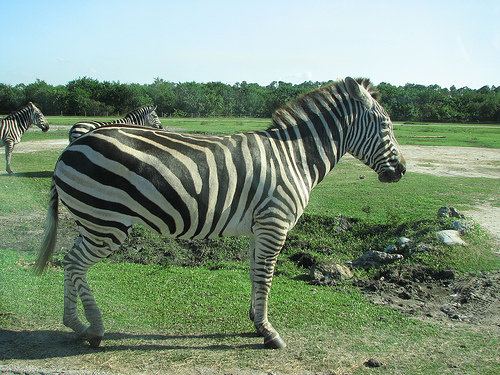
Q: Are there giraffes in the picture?
A: No, there are no giraffes.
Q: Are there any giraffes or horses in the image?
A: No, there are no giraffes or horses.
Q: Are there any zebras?
A: Yes, there is a zebra.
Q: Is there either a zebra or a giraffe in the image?
A: Yes, there is a zebra.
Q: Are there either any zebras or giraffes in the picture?
A: Yes, there is a zebra.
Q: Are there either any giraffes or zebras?
A: Yes, there is a zebra.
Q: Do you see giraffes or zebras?
A: Yes, there is a zebra.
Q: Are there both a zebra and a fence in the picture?
A: No, there is a zebra but no fences.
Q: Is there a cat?
A: No, there are no cats.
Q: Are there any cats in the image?
A: No, there are no cats.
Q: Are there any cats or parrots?
A: No, there are no cats or parrots.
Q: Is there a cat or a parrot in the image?
A: No, there are no cats or parrots.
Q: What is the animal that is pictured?
A: The animal is a zebra.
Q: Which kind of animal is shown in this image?
A: The animal is a zebra.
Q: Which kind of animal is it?
A: The animal is a zebra.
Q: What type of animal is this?
A: That is a zebra.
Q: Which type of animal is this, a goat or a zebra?
A: That is a zebra.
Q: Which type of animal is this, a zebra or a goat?
A: That is a zebra.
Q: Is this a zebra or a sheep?
A: This is a zebra.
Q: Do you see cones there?
A: No, there are no cones.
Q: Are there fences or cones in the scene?
A: No, there are no cones or fences.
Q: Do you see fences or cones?
A: No, there are no cones or fences.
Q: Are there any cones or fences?
A: No, there are no cones or fences.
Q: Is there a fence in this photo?
A: No, there are no fences.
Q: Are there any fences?
A: No, there are no fences.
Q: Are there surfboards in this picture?
A: No, there are no surfboards.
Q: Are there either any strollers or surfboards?
A: No, there are no surfboards or strollers.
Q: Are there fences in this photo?
A: No, there are no fences.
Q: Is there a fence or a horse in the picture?
A: No, there are no fences or horses.